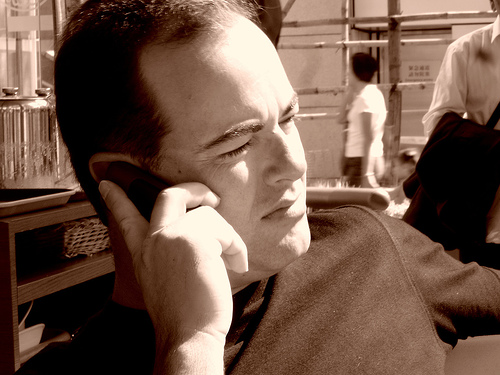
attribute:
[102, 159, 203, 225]
cell phone — black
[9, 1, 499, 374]
man — squinting, here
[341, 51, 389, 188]
person — walking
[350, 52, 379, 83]
hat — black, knit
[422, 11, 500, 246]
shirt — collared, white, long sleeve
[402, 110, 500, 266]
coat — dark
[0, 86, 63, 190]
canister — metal, shiny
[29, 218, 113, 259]
basket — wicker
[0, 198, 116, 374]
shelf — wooden, brown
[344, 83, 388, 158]
shirt — white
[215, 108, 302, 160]
eyes — closed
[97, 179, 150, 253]
finger — extended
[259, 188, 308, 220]
mouth — closed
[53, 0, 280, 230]
hair — dark, black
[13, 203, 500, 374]
shirt — dark, black